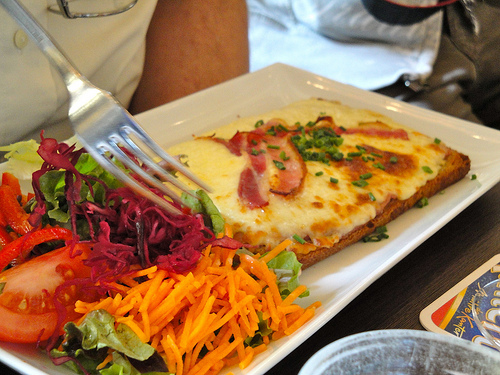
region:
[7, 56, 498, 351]
a white plate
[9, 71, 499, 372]
a plate of food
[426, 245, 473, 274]
the wood table under the plate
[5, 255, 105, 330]
a sliced tomato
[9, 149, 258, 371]
a salad on the plate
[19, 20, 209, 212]
a silver fork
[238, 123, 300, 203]
bacon pieces on the cheese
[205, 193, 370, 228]
cheese on the food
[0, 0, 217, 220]
a fork digging into a delicious looking meal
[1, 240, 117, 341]
sliced tomatoes are part of this meal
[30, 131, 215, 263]
red cabbage is part of this meal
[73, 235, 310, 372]
grated squash is part of this meal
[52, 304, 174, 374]
lettuce is part of this meal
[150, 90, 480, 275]
a little personal-size pizza is part of the meal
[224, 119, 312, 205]
a slice of bacon tops the pizza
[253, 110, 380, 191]
chopped green onion garnishes the pizza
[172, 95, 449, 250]
the pizza has lots of melted cheese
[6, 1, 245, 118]
a person sitting at the table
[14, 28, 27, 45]
a white button on the shirt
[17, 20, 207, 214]
a fork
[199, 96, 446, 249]
cheese and toppings on bread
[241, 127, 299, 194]
bacon on the bread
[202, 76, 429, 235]
cheese on the bread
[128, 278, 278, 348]
shredded carrots on the salad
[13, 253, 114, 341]
a tomato on the salad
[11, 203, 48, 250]
red peppers on the salad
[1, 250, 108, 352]
Tomato slice on plate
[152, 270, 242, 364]
Shredded cheddar cheese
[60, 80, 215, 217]
Long teeth silver fork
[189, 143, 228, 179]
Melted mozzarella cheese on bread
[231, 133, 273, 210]
Piece of cooked bacon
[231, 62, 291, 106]
White shiny ceramic plate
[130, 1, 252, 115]
Hairy caucasian left arm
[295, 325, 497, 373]
Round ceramic colored bowl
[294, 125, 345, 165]
Cuts of green vegetable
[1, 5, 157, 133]
Beige buttoned fabric shirt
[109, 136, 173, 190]
SILVER FORK OVER THE PLATE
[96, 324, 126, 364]
LETTUCE ON THE PLATE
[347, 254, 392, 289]
WHITE PLATE ON THE TABLE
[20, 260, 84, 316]
TOMATOES ON THE SIDE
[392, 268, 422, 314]
TABLE MADE OUT OF WOOD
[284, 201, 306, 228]
CHEESE ON TOP OF PIZZA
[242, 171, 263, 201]
BACON SLICED ON THE TOP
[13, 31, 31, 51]
BUTTON ON THE SHIRT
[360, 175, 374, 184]
GREEN CHOPPED ONION ON TOP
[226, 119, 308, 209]
Piece of bacon with chopped chives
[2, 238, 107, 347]
Red ripe juicy tomato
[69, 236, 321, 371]
Bright orange julienned carrots on lettuce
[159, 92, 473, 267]
Bacon cheesy pizza with chopped chives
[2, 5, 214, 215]
A four-pronged fork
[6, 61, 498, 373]
A delicious and healthy lunch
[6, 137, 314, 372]
A fresh and colorful salad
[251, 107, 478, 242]
chopped chives to top it off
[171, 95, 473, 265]
Bread topped with cheese and bacon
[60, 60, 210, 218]
a silver fork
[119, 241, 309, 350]
A portion of shredded carrots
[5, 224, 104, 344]
A slice of red tomato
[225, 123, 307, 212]
A piece of bacon on the pizza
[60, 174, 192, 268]
red cabbage under the fork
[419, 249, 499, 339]
a coaster on the table